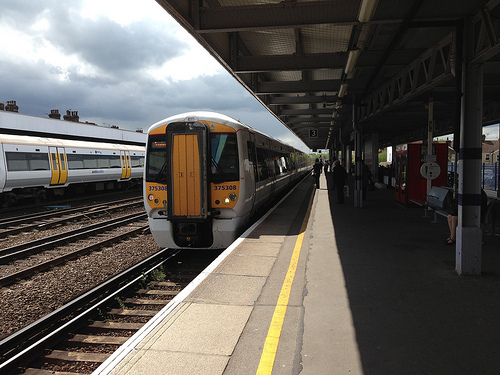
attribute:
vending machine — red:
[392, 137, 457, 212]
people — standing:
[306, 144, 347, 201]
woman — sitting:
[441, 183, 477, 245]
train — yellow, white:
[139, 125, 320, 239]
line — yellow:
[261, 185, 325, 372]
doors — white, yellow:
[47, 149, 69, 181]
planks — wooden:
[33, 276, 181, 371]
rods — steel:
[23, 245, 167, 353]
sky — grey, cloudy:
[28, 15, 170, 104]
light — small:
[214, 195, 233, 213]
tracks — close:
[10, 255, 165, 357]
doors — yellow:
[166, 118, 204, 221]